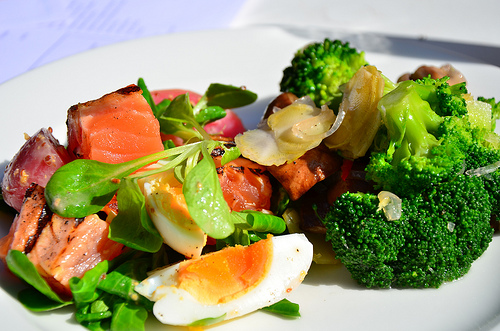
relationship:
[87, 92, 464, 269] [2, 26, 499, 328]
food on plate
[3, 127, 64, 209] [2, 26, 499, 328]
pieces on plate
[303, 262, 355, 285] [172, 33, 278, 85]
shadow on plate